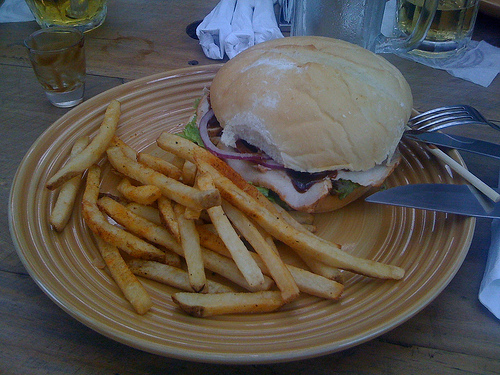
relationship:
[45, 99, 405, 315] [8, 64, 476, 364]
french fries are on plate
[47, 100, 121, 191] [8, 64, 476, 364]
french fry on plate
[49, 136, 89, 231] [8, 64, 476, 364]
french fry on plate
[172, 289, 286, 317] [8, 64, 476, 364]
french fry on plate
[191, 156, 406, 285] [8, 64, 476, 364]
french fries on plate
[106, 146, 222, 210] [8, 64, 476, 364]
french fry on plate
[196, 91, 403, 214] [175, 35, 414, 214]
ham in sandwich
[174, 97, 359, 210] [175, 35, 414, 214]
lettuce in sandwich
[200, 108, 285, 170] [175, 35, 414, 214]
onion in sandwich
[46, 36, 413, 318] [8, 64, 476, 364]
meal on plate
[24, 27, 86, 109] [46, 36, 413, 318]
drink next to meal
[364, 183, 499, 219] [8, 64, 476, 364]
blade resting on plate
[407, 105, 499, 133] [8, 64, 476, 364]
fork resting on plate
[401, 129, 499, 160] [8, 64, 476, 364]
butterknife resting on plate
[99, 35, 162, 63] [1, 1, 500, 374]
stain on table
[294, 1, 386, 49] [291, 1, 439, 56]
water in pitcher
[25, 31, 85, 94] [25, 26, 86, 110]
drink in glass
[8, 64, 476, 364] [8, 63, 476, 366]
plate decorated with lines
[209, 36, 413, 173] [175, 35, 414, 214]
top bun on sandwich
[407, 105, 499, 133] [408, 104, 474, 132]
fork has tines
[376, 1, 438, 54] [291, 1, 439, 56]
handle on pitcher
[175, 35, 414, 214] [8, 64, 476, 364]
sandwich on plate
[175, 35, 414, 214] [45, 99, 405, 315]
sandwich near french fries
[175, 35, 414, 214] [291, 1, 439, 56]
sandwich near pitcher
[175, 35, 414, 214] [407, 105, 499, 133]
sandwich near fork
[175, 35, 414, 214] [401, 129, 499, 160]
sandwich near butterknife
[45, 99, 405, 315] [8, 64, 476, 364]
french fries on plate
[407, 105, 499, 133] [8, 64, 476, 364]
fork leaning on plate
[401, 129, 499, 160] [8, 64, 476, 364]
butterknife leaning on plate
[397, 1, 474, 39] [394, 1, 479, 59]
beer in pitcher